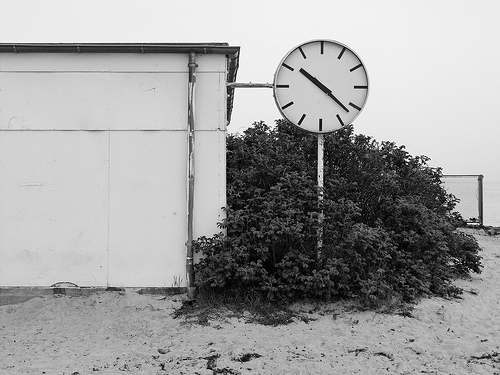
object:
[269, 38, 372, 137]
clock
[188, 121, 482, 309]
bush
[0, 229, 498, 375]
ground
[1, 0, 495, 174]
sky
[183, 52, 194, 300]
pipe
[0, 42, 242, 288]
building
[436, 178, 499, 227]
water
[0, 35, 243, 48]
gutter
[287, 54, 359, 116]
numbers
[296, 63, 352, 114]
hands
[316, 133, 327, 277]
pole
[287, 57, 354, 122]
face